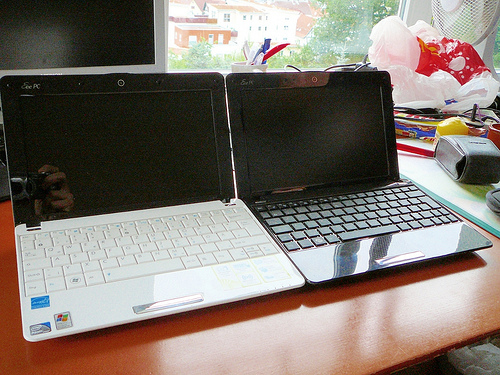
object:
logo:
[19, 82, 40, 91]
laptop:
[1, 72, 307, 344]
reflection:
[7, 166, 75, 218]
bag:
[365, 15, 499, 115]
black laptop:
[225, 70, 493, 285]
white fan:
[427, 0, 500, 80]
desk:
[0, 180, 500, 375]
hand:
[33, 165, 75, 221]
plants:
[183, 41, 230, 70]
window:
[163, 0, 498, 77]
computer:
[1, 68, 303, 348]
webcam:
[117, 79, 125, 87]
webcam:
[311, 76, 318, 83]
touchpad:
[133, 293, 203, 313]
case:
[433, 134, 499, 185]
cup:
[231, 60, 267, 74]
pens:
[250, 42, 290, 65]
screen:
[20, 88, 220, 215]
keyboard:
[17, 205, 277, 295]